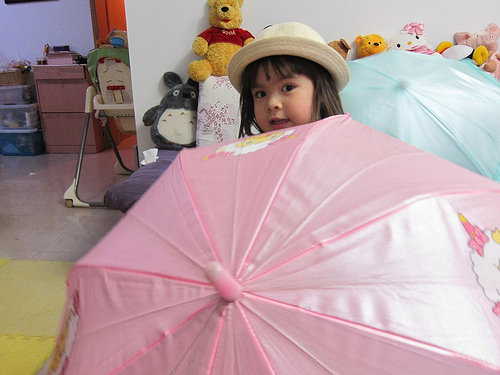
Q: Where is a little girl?
A: Behind pink umbrella.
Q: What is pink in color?
A: An umbrella.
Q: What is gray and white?
A: Stuffed animal.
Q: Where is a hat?
A: On little girl's head.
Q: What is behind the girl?
A: Blue umbrella.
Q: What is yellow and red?
A: Winnie the Pooh doll.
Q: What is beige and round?
A: Girl's hat.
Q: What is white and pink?
A: Hello Kitty doll.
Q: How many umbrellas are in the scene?
A: Two.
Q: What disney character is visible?
A: Pooh.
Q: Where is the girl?
A: Behind umbrella.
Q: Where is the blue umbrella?
A: Behind the girl.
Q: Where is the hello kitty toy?
A: Next to pooh.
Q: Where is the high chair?
A: Room behind the girl.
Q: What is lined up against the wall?
A: Stuffed toys.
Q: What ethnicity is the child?
A: Asian.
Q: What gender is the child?
A: Girl.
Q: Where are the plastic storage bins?
A: Back room next to brown drawers.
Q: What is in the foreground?
A: A pink umbrella.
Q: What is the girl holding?
A: An umbrella.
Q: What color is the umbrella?
A: Pink.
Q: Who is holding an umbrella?
A: The girl.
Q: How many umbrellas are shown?
A: Two.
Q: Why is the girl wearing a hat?
A: For fun.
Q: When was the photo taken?
A: Daytime.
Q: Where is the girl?
A: Behind the umbrella.